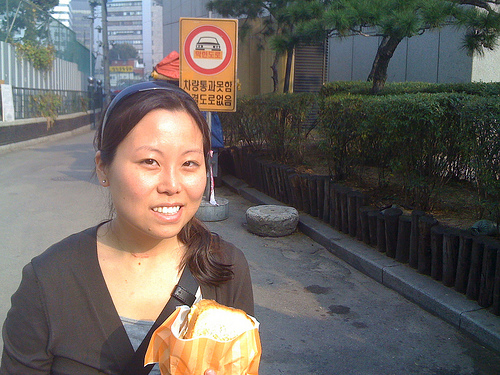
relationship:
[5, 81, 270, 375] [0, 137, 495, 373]
girl walking on ground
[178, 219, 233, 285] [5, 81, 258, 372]
pony tail on girl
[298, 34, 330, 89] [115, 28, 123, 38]
shutter on window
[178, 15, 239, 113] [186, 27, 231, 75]
sign has circle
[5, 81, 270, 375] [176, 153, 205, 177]
girl has left eye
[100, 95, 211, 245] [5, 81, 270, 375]
face of girl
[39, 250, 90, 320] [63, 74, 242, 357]
shirt on lady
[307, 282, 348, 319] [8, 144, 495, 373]
shadow on ground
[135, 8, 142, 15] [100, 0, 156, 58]
window on building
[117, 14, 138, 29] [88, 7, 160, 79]
window on building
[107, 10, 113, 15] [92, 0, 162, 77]
window on building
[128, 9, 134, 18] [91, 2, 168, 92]
window on building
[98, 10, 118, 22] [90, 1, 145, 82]
window on building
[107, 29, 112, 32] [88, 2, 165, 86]
window on building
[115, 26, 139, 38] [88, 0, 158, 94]
window on building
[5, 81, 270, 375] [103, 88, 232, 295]
girl has hair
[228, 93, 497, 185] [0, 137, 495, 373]
hedge near ground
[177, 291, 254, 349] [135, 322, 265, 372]
sandwich in bag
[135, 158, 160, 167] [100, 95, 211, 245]
eye in face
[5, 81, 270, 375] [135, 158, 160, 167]
girl has eye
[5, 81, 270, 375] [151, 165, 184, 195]
girl has nose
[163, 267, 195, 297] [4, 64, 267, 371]
strap on woman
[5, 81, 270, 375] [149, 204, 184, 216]
girl has teeth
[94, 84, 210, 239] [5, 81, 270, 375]
head on girl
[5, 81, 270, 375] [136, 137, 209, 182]
girl has eyes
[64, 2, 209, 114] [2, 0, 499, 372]
building in city